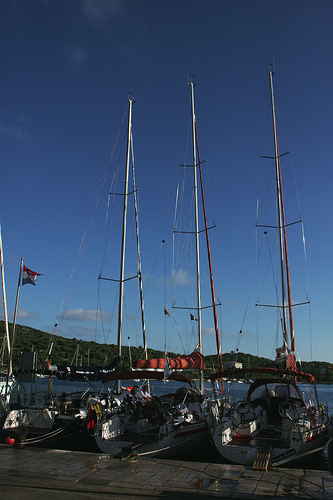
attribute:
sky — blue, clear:
[15, 9, 301, 95]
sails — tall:
[115, 79, 311, 409]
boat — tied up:
[91, 106, 207, 463]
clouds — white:
[3, 1, 252, 347]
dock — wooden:
[2, 444, 332, 499]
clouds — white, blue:
[61, 0, 119, 74]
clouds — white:
[159, 266, 194, 292]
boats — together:
[0, 53, 332, 467]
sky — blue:
[2, 2, 331, 207]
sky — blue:
[0, 0, 332, 363]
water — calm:
[0, 369, 333, 410]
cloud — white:
[164, 267, 190, 282]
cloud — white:
[63, 307, 110, 322]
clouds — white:
[1, 268, 331, 356]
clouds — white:
[11, 243, 211, 339]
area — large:
[4, 10, 331, 367]